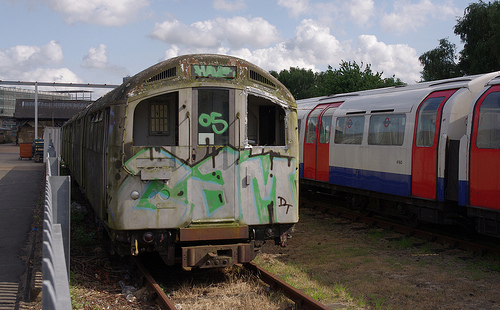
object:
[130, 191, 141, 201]
light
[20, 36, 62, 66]
cloud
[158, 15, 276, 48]
cloud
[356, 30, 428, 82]
cloud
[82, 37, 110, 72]
cloud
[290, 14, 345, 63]
cloud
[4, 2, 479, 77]
sky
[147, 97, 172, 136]
window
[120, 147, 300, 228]
paint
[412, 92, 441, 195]
paint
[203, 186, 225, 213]
graffiti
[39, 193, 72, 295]
barrier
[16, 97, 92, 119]
cover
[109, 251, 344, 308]
track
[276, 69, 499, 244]
train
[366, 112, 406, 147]
window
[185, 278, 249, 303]
grass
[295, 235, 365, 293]
grass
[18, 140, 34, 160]
container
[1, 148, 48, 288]
ground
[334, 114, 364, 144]
window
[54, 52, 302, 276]
train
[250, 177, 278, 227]
writtings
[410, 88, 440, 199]
door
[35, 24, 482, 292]
railway station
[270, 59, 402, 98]
tree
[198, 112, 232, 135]
green lettering